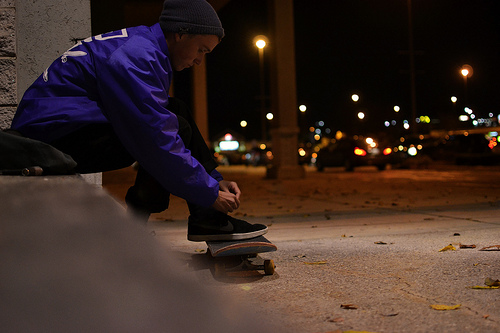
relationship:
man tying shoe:
[10, 0, 269, 241] [186, 212, 269, 243]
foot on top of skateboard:
[186, 208, 267, 243] [203, 234, 277, 278]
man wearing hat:
[10, 0, 269, 241] [156, 0, 226, 40]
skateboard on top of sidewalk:
[203, 234, 277, 278] [104, 168, 499, 332]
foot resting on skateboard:
[186, 208, 267, 243] [203, 234, 277, 278]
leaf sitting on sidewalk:
[476, 240, 499, 252] [104, 168, 499, 332]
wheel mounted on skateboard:
[211, 260, 227, 279] [203, 234, 277, 278]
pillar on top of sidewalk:
[261, 1, 307, 183] [104, 168, 499, 332]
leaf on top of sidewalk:
[476, 240, 499, 252] [104, 168, 499, 332]